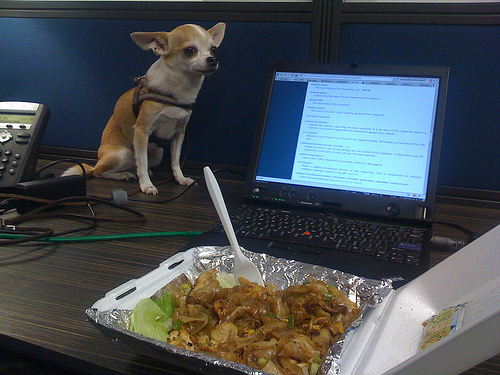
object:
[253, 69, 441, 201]
image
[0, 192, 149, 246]
cable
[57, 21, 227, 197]
chihuahua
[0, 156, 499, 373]
table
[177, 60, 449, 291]
laptop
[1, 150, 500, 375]
desk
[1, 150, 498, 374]
wooden table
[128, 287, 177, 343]
lettuce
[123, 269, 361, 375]
foil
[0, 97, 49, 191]
electronic device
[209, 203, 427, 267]
buttons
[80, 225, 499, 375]
container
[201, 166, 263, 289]
fork